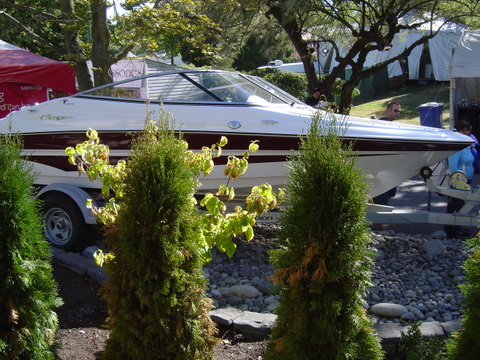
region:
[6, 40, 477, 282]
this is a speed boat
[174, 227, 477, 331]
there are rocks on the ground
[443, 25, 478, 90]
a white canopy tent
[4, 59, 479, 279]
the boat is on a trailer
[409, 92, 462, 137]
a blue recycling bin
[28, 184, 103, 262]
a wheel of the boat trailer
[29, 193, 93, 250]
the tire is black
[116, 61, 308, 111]
this is the boat's windshield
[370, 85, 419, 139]
this man is wearing sunglasses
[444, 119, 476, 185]
this woman is wearing a blue shirt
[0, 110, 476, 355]
evergreen shrubs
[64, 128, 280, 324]
green bush with drooping leaves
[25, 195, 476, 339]
large gravel pad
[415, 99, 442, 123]
blue plastic garbage barrel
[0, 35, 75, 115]
red and tan tent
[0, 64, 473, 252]
small boat on trailer in campground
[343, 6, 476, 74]
large white camping tent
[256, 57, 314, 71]
white truck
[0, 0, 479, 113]
large shade trees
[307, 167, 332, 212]
Part of the green tree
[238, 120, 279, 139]
Part of the boat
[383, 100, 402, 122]
The head of the person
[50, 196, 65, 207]
Part of the tire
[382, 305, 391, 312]
Part of the stone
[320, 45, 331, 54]
A light in distance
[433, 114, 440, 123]
Part of the trashcan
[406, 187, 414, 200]
Part of the ground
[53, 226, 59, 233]
Part of the wheel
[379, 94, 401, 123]
A man wearing dark sunglasses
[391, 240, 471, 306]
Gray rocks on the ground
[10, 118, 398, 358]
Small green trees in a line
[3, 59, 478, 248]
A boat on its cart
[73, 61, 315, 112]
Windshield of a small boat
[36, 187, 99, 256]
The wheel of a boat cart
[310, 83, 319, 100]
A man is wearing a black hat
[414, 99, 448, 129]
Blue plastic container with lid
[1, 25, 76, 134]
The corner of a red tent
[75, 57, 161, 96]
White sign at a distance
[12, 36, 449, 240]
a boat that is parked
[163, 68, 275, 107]
the window of a boat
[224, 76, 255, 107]
the steering wheel of a boat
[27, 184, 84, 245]
the wheel of a boat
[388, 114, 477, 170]
the front of a boat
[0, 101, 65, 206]
the back of a boat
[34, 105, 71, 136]
the logo of a boat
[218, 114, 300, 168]
a big purple and white stripe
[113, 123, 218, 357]
a tall shrub in a driveway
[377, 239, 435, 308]
a driveway full of rocks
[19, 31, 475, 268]
a white speed boat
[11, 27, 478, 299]
this is a speed boat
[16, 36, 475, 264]
the boat is on a trailer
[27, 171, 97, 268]
the wheel of a trailer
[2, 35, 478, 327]
the boat and trailer are parked on rocks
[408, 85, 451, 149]
a blue recycling can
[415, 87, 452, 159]
a blue garbage bin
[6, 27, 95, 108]
this is a red canopy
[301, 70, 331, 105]
a man next to a tree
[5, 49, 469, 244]
boat parked in the driveway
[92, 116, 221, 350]
tree in the driveway